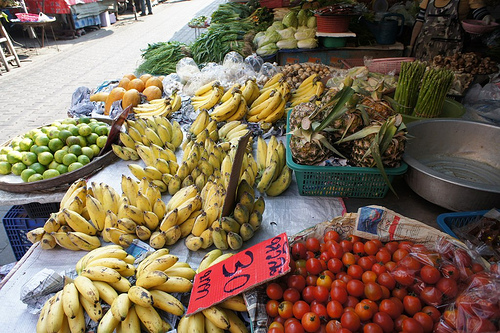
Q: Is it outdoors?
A: Yes, it is outdoors.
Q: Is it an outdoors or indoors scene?
A: It is outdoors.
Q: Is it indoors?
A: No, it is outdoors.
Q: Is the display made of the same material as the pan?
A: No, the display is made of plastic and the pan is made of metal.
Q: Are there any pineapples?
A: Yes, there are pineapples.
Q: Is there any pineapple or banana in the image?
A: Yes, there are pineapples.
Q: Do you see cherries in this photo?
A: No, there are no cherries.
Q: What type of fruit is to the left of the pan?
A: The fruits are pineapples.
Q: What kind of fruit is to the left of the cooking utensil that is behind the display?
A: The fruits are pineapples.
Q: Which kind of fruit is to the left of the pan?
A: The fruits are pineapples.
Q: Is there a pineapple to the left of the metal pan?
A: Yes, there are pineapples to the left of the pan.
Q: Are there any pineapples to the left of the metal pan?
A: Yes, there are pineapples to the left of the pan.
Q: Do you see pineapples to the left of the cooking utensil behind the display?
A: Yes, there are pineapples to the left of the pan.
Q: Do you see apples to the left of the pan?
A: No, there are pineapples to the left of the pan.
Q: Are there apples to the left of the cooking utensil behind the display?
A: No, there are pineapples to the left of the pan.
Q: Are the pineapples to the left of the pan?
A: Yes, the pineapples are to the left of the pan.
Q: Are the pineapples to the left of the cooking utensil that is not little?
A: Yes, the pineapples are to the left of the pan.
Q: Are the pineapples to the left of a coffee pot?
A: No, the pineapples are to the left of the pan.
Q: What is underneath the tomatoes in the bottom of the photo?
A: The newspaper is underneath the tomatoes.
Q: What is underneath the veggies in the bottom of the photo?
A: The newspaper is underneath the tomatoes.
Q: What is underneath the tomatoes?
A: The newspaper is underneath the tomatoes.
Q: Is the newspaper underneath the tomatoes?
A: Yes, the newspaper is underneath the tomatoes.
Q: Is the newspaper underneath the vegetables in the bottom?
A: Yes, the newspaper is underneath the tomatoes.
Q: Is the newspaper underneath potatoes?
A: No, the newspaper is underneath the tomatoes.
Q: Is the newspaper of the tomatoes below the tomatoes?
A: Yes, the newspaper is below the tomatoes.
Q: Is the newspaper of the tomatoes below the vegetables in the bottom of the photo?
A: Yes, the newspaper is below the tomatoes.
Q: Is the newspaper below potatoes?
A: No, the newspaper is below the tomatoes.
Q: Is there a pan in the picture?
A: Yes, there is a pan.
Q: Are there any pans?
A: Yes, there is a pan.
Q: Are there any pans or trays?
A: Yes, there is a pan.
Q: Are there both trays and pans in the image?
A: Yes, there are both a pan and a tray.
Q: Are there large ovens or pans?
A: Yes, there is a large pan.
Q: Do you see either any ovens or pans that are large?
A: Yes, the pan is large.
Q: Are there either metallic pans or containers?
A: Yes, there is a metal pan.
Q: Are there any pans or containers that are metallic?
A: Yes, the pan is metallic.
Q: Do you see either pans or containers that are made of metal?
A: Yes, the pan is made of metal.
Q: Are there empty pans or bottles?
A: Yes, there is an empty pan.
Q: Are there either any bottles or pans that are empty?
A: Yes, the pan is empty.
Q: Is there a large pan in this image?
A: Yes, there is a large pan.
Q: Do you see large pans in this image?
A: Yes, there is a large pan.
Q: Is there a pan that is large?
A: Yes, there is a pan that is large.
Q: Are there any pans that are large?
A: Yes, there is a pan that is large.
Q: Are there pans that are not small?
A: Yes, there is a large pan.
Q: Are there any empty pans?
A: Yes, there is an empty pan.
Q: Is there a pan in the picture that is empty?
A: Yes, there is a pan that is empty.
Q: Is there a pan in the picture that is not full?
A: Yes, there is a empty pan.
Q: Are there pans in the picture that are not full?
A: Yes, there is a empty pan.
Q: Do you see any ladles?
A: No, there are no ladles.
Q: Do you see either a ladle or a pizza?
A: No, there are no ladles or pizzas.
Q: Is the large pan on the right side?
A: Yes, the pan is on the right of the image.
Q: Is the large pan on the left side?
A: No, the pan is on the right of the image.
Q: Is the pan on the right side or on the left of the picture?
A: The pan is on the right of the image.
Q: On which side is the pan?
A: The pan is on the right of the image.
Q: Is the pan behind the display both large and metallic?
A: Yes, the pan is large and metallic.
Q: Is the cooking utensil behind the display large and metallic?
A: Yes, the pan is large and metallic.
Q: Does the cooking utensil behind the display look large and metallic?
A: Yes, the pan is large and metallic.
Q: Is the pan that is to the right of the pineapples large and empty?
A: Yes, the pan is large and empty.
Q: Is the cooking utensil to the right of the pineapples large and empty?
A: Yes, the pan is large and empty.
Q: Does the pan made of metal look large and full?
A: No, the pan is large but empty.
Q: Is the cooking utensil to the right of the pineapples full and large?
A: No, the pan is large but empty.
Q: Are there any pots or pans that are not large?
A: No, there is a pan but it is large.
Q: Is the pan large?
A: Yes, the pan is large.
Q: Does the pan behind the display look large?
A: Yes, the pan is large.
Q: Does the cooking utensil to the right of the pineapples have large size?
A: Yes, the pan is large.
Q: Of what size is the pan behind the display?
A: The pan is large.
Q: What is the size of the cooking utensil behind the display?
A: The pan is large.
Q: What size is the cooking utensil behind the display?
A: The pan is large.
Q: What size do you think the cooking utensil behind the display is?
A: The pan is large.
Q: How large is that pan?
A: The pan is large.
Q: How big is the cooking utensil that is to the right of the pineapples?
A: The pan is large.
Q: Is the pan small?
A: No, the pan is large.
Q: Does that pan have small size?
A: No, the pan is large.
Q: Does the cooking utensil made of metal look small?
A: No, the pan is large.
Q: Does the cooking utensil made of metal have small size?
A: No, the pan is large.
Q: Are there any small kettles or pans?
A: No, there is a pan but it is large.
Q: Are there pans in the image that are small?
A: No, there is a pan but it is large.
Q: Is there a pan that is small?
A: No, there is a pan but it is large.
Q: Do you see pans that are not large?
A: No, there is a pan but it is large.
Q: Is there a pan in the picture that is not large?
A: No, there is a pan but it is large.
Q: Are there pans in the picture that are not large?
A: No, there is a pan but it is large.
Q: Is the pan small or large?
A: The pan is large.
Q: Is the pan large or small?
A: The pan is large.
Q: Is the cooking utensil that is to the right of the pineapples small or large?
A: The pan is large.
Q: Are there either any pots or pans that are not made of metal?
A: No, there is a pan but it is made of metal.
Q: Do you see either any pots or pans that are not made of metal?
A: No, there is a pan but it is made of metal.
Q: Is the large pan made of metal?
A: Yes, the pan is made of metal.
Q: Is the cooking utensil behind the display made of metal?
A: Yes, the pan is made of metal.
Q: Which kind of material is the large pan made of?
A: The pan is made of metal.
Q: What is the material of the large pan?
A: The pan is made of metal.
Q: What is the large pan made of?
A: The pan is made of metal.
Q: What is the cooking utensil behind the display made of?
A: The pan is made of metal.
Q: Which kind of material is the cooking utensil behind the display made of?
A: The pan is made of metal.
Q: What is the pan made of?
A: The pan is made of metal.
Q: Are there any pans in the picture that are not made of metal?
A: No, there is a pan but it is made of metal.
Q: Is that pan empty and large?
A: Yes, the pan is empty and large.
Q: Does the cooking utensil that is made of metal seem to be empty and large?
A: Yes, the pan is empty and large.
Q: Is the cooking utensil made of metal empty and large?
A: Yes, the pan is empty and large.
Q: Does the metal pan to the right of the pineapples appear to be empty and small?
A: No, the pan is empty but large.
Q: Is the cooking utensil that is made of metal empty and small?
A: No, the pan is empty but large.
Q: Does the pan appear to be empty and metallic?
A: Yes, the pan is empty and metallic.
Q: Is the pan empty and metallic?
A: Yes, the pan is empty and metallic.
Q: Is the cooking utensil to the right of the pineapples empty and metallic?
A: Yes, the pan is empty and metallic.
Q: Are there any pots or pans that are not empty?
A: No, there is a pan but it is empty.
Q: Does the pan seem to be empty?
A: Yes, the pan is empty.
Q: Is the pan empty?
A: Yes, the pan is empty.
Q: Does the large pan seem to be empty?
A: Yes, the pan is empty.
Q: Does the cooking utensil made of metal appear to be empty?
A: Yes, the pan is empty.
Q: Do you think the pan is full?
A: No, the pan is empty.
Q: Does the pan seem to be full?
A: No, the pan is empty.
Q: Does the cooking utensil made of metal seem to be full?
A: No, the pan is empty.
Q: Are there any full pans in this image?
A: No, there is a pan but it is empty.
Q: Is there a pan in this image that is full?
A: No, there is a pan but it is empty.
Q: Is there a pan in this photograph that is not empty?
A: No, there is a pan but it is empty.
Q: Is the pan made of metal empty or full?
A: The pan is empty.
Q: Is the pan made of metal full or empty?
A: The pan is empty.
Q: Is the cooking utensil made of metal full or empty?
A: The pan is empty.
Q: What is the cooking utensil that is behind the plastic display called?
A: The cooking utensil is a pan.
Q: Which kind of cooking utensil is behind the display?
A: The cooking utensil is a pan.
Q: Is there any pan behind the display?
A: Yes, there is a pan behind the display.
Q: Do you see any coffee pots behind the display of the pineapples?
A: No, there is a pan behind the display.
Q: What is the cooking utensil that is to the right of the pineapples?
A: The cooking utensil is a pan.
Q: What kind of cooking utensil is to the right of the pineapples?
A: The cooking utensil is a pan.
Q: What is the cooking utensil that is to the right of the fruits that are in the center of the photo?
A: The cooking utensil is a pan.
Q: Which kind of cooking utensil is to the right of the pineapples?
A: The cooking utensil is a pan.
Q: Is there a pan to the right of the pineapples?
A: Yes, there is a pan to the right of the pineapples.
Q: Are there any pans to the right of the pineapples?
A: Yes, there is a pan to the right of the pineapples.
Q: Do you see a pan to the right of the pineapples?
A: Yes, there is a pan to the right of the pineapples.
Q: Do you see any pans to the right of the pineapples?
A: Yes, there is a pan to the right of the pineapples.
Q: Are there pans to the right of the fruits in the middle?
A: Yes, there is a pan to the right of the pineapples.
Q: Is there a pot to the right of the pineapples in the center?
A: No, there is a pan to the right of the pineapples.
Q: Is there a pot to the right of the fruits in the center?
A: No, there is a pan to the right of the pineapples.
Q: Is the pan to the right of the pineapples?
A: Yes, the pan is to the right of the pineapples.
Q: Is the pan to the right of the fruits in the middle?
A: Yes, the pan is to the right of the pineapples.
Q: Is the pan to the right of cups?
A: No, the pan is to the right of the pineapples.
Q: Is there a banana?
A: Yes, there are bananas.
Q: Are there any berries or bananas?
A: Yes, there are bananas.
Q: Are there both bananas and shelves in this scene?
A: No, there are bananas but no shelves.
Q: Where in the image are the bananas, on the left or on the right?
A: The bananas are on the left of the image.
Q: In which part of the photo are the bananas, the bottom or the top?
A: The bananas are in the bottom of the image.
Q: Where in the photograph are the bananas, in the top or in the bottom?
A: The bananas are in the bottom of the image.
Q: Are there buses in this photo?
A: No, there are no buses.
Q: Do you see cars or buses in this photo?
A: No, there are no buses or cars.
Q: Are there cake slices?
A: No, there are no cake slices.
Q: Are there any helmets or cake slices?
A: No, there are no cake slices or helmets.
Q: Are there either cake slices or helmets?
A: No, there are no cake slices or helmets.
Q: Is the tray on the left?
A: Yes, the tray is on the left of the image.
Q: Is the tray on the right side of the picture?
A: No, the tray is on the left of the image.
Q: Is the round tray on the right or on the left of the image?
A: The tray is on the left of the image.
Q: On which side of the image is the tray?
A: The tray is on the left of the image.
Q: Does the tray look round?
A: Yes, the tray is round.